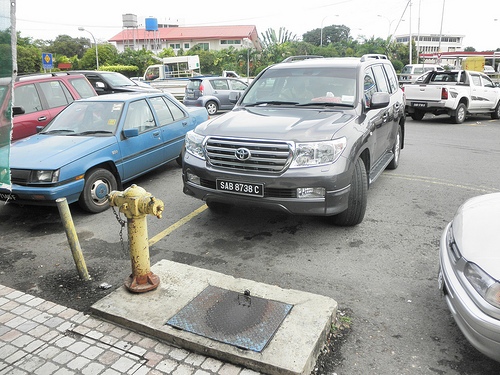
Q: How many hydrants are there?
A: One.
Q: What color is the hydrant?
A: Pale yellow.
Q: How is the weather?
A: Cloudy.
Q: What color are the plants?
A: Green.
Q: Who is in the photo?
A: No one.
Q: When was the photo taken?
A: Daytime.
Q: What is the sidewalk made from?
A: Bricks.